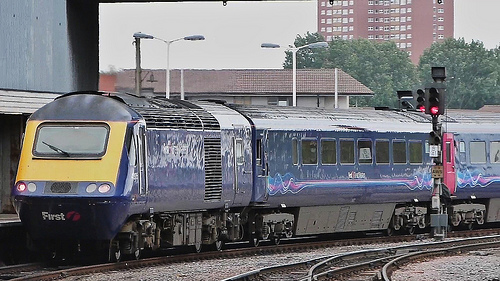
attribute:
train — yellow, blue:
[12, 85, 496, 245]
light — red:
[413, 69, 463, 136]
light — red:
[425, 102, 443, 118]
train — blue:
[253, 98, 498, 219]